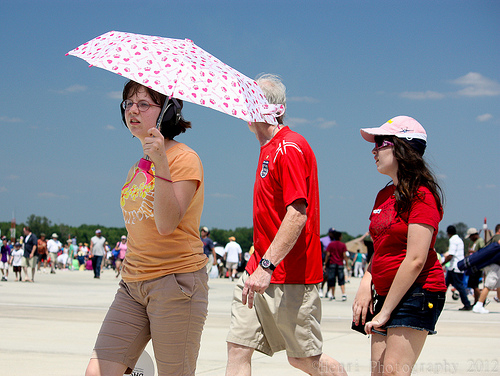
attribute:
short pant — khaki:
[95, 263, 208, 374]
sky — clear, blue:
[277, 14, 377, 56]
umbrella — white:
[55, 7, 305, 157]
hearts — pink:
[127, 46, 155, 62]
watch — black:
[256, 256, 279, 276]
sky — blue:
[4, 3, 497, 228]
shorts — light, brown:
[88, 267, 205, 374]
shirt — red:
[206, 133, 356, 293]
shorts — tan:
[224, 270, 323, 358]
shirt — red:
[364, 182, 446, 295]